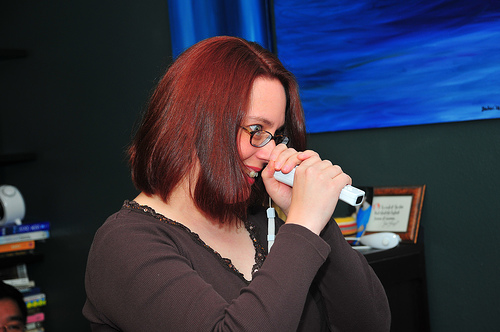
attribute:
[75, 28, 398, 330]
woman — red-headed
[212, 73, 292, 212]
face — pink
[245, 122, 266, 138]
eyes — open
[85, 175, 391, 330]
shirt — long-sleeved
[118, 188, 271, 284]
neckline — crocheted, vee-shaped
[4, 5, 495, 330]
wall — dark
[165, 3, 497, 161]
abstract — blue